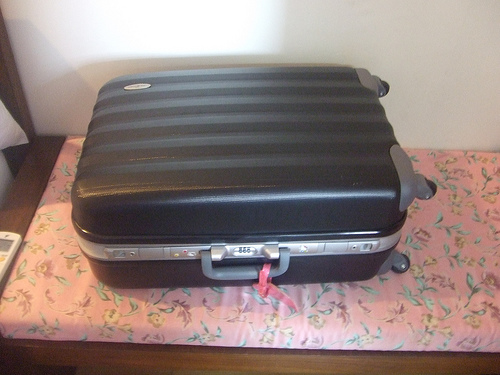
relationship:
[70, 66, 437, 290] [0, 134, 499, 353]
case on cover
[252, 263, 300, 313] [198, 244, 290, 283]
pink ribbon on handle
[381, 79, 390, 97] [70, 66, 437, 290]
wheel of case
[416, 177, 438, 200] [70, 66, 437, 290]
wheel of case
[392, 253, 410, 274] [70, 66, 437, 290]
wheel of case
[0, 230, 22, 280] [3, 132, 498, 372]
control on table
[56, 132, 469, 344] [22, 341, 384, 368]
mat on table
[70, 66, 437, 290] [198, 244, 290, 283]
case has handle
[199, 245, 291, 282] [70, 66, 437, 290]
gray handle on case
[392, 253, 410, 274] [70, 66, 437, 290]
wheel on case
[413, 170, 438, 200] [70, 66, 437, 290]
wheel on case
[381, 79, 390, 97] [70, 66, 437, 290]
wheel on case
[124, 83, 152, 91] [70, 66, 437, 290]
disk on case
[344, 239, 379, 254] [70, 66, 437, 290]
latch on case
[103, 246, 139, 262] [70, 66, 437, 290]
latch on case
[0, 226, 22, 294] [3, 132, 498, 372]
control on table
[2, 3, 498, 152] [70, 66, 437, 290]
wall behind case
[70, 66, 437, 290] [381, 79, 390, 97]
case has wheel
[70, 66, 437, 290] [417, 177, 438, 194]
case has wheel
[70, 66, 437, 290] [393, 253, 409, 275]
case has wheel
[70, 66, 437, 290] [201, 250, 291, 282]
case has handle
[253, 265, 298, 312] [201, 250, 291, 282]
pink ribbon attached to handle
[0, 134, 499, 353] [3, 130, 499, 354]
cover has cover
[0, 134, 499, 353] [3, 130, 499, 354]
cover on cover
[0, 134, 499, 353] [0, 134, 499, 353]
cover on cover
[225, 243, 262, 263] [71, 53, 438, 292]
combination lock on case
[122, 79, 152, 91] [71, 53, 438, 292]
disk attached to case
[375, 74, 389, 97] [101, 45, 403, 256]
wheel attached to luggage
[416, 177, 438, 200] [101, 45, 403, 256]
wheel attached to luggage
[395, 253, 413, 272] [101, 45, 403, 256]
wheel attached to luggage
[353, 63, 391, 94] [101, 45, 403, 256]
bracket attached to luggage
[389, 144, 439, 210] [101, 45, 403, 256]
bracket attached to luggage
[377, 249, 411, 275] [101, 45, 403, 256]
bracket attached to luggage